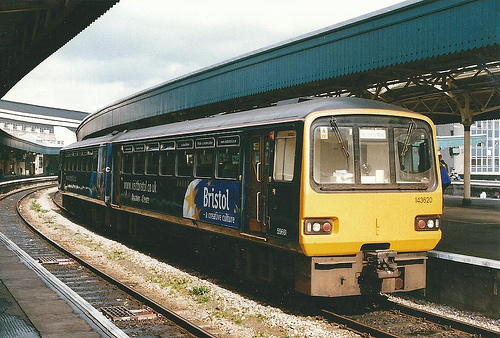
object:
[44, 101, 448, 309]
train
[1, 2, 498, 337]
railway station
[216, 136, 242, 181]
window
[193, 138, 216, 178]
window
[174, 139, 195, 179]
window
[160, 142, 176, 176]
window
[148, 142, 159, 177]
window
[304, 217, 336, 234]
headlights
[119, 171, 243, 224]
advertisement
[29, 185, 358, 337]
rocks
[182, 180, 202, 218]
stars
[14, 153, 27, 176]
people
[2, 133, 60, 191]
platform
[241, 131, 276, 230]
door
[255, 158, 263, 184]
handles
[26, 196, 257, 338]
grass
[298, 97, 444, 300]
front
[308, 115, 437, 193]
windshield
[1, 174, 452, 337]
tracks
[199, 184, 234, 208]
words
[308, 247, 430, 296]
coupling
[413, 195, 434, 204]
number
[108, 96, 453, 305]
lead car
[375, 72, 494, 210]
supports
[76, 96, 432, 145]
roof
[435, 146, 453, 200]
person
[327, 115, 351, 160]
wipers